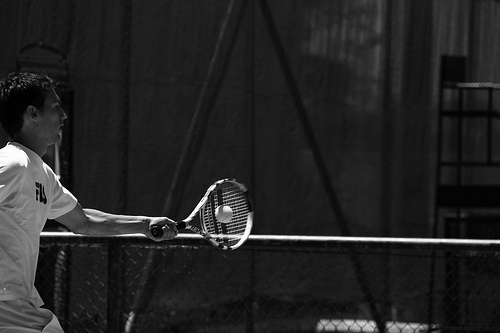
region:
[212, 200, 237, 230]
tennis ball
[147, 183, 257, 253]
black and white tennis racket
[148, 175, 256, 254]
tennis racket hitting a tennis ball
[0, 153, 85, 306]
white shirt with black logo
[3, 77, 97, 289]
man wearing white shirt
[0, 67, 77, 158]
man with short hair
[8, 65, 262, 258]
man holding a tennis racket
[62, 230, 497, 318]
black and white net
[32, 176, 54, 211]
black logo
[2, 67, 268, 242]
man playing tennis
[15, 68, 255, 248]
a man holding a tennis racket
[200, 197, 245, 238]
a tennis ball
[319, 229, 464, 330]
a chain link fence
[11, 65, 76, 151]
a man with short hair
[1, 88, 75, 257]
a man wearing a white shirt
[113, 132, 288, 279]
a man hitting a tennis ball with a racket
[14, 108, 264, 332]
a man playing tennis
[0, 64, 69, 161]
a man with dark hair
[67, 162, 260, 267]
a man using a tennis racket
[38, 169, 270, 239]
a man with his arm stretched out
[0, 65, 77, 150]
the head of a man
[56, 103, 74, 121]
the nose of a man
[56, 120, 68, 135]
the mouth of a man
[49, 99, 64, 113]
the eye of a man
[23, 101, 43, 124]
the ear of a man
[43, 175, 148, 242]
the arm of a man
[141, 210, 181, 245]
the hand of a man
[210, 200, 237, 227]
a tennis ball in the air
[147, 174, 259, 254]
a tennis racket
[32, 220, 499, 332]
a chain link fence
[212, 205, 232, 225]
tennis ball in the air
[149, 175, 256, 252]
tennis racket hitting a ball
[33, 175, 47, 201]
print on the front of a shirt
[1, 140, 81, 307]
shirt on a tennis player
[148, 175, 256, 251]
tennis racket in a player's hand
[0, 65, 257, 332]
tennis player swing his racket at a ball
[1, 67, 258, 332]
young tennis player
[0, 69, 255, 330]
young man playing tennis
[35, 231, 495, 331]
net going across a tennis court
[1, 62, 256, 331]
man hitting a tennis ball with his racket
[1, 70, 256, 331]
Man hitting tennis ball with racket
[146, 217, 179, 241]
Black tennis racket handle in man's hand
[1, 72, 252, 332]
Man wearing white shirt holding tennis racket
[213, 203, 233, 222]
Tennis ball touching tennis racket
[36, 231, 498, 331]
Chain link fence in background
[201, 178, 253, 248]
Strings on tennis racket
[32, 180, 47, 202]
Black logo on white shirt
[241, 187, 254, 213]
Black stripe on tennis racket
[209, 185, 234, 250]
Black stripes on tennis racket strings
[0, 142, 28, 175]
Light reflecting off of man's shoulder